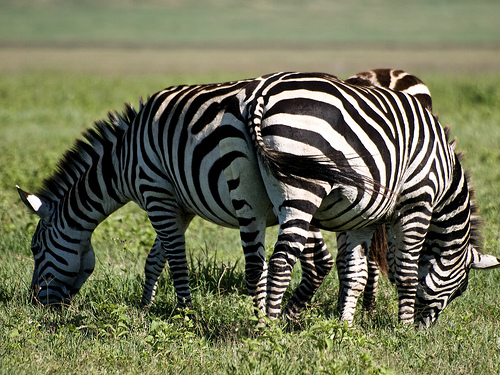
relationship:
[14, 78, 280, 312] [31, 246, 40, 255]
zebra has eye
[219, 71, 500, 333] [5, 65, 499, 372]
zebra eating grass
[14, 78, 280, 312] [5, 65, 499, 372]
zebra eating grass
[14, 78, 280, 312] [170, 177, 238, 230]
zebra has zebra`s stomach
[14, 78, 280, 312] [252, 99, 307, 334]
zebra has leg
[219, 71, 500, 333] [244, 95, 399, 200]
zebra has tail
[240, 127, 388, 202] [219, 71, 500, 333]
tail on zebra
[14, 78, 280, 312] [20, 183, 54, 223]
zebra has ear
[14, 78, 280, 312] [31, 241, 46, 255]
zebra has eye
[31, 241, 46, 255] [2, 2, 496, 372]
eye looking towards ground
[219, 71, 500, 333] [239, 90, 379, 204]
zebra has tail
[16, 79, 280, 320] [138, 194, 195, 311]
zebra has leg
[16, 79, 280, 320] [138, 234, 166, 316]
zebra has leg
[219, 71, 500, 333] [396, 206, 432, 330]
zebra has front legs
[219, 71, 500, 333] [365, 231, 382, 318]
zebra has front legs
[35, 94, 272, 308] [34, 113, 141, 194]
zebra has mane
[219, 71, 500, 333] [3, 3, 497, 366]
zebra eating grass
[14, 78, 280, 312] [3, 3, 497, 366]
zebra eating grass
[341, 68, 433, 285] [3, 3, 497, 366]
zebra eating grass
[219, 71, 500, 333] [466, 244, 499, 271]
zebra has ear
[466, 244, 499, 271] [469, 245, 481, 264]
ear has stripes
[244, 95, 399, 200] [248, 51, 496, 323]
tail hidden behind zebra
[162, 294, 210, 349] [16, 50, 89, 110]
weed in grass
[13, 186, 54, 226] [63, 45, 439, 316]
ear of zebra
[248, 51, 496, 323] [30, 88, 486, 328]
zebra in foreground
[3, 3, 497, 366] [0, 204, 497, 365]
grass in forefront